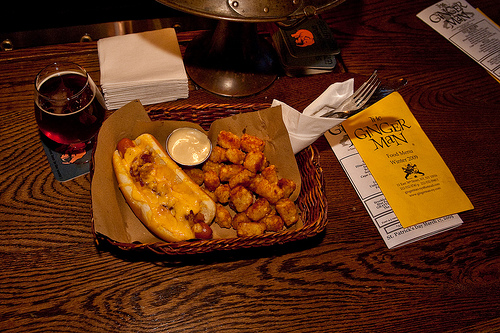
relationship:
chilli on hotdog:
[117, 143, 197, 222] [111, 132, 219, 245]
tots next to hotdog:
[186, 132, 299, 233] [111, 132, 219, 245]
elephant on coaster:
[291, 30, 314, 47] [277, 19, 340, 73]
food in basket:
[114, 131, 302, 236] [88, 99, 329, 257]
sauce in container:
[167, 128, 210, 163] [160, 126, 211, 169]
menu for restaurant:
[291, 88, 472, 253] [351, 114, 415, 156]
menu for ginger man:
[291, 88, 472, 253] [351, 114, 415, 156]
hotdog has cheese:
[111, 132, 219, 245] [110, 143, 208, 237]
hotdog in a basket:
[111, 132, 219, 245] [88, 99, 329, 257]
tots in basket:
[186, 132, 299, 233] [88, 99, 329, 257]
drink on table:
[34, 57, 108, 147] [3, 1, 498, 331]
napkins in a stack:
[93, 27, 199, 112] [91, 29, 192, 105]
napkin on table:
[269, 77, 352, 156] [3, 1, 498, 331]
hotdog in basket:
[111, 132, 219, 245] [88, 99, 329, 257]